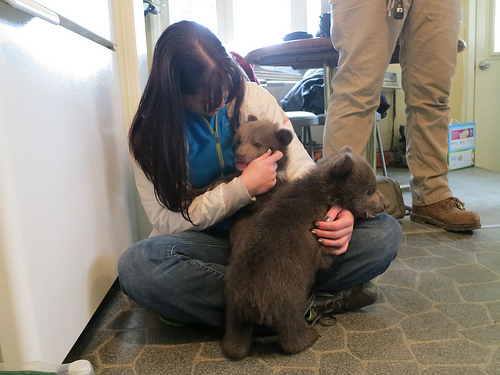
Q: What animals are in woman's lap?
A: Bear cubs.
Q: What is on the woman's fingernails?
A: Green polish.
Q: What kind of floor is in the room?
A: Stone floor.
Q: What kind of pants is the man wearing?
A: Khakis.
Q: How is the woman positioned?
A: Indian style.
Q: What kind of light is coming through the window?
A: Sunlight.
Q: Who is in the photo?
A: A lady.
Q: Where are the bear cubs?
A: In the woman's lap.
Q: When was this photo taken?
A: During the day.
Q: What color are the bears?
A: Brown.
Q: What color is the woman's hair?
A: Brown.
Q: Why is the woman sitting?
A: To hold the bears.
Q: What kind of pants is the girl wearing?
A: Blue jeans.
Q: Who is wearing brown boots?
A: The man.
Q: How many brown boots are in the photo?
A: 2.